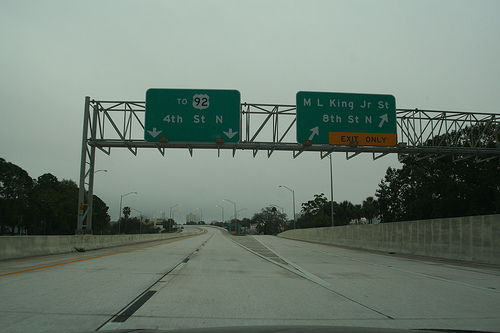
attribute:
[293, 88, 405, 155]
street sign — white, green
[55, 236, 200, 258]
line — yellow, painted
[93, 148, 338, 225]
street lights — on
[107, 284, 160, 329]
line — black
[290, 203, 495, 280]
barrier — concrete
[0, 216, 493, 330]
long highway — empty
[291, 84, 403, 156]
sign — large, green, white, black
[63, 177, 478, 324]
roadway — empty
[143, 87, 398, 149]
signs — green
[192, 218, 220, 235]
ramp — exit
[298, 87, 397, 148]
sign — exit only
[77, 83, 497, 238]
structure — metal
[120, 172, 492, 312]
highway — concrete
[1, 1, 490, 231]
sky — cloudy, grey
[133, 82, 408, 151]
red b — highway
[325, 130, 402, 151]
sign — says Exit Only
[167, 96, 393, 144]
printing — yellow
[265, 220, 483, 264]
wall — concrete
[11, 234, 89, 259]
barrier — concrete